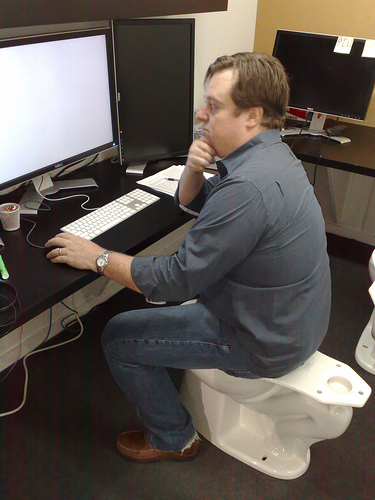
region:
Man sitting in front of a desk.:
[73, 1, 356, 491]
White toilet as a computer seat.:
[155, 318, 365, 493]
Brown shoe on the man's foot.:
[96, 420, 226, 470]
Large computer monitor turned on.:
[0, 8, 131, 178]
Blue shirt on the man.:
[124, 121, 344, 384]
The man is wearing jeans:
[90, 282, 296, 451]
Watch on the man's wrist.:
[94, 243, 118, 285]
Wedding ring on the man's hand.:
[55, 245, 68, 256]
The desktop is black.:
[3, 115, 257, 337]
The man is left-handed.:
[0, 211, 132, 280]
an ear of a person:
[246, 103, 262, 131]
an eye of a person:
[204, 95, 224, 113]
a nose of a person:
[194, 102, 209, 122]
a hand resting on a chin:
[184, 134, 220, 175]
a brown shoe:
[110, 431, 212, 461]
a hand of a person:
[44, 231, 93, 271]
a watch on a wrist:
[92, 246, 113, 275]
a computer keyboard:
[60, 200, 165, 231]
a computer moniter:
[276, 23, 374, 141]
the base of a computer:
[21, 173, 100, 212]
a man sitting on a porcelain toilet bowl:
[41, 43, 369, 484]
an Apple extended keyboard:
[51, 184, 166, 248]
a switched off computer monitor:
[263, 25, 373, 147]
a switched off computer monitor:
[106, 14, 195, 173]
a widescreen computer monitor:
[0, 25, 117, 216]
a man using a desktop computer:
[2, 23, 334, 465]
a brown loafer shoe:
[109, 428, 204, 466]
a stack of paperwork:
[136, 155, 211, 203]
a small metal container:
[0, 201, 24, 233]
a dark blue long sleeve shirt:
[126, 140, 338, 380]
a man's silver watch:
[90, 245, 114, 280]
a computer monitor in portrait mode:
[103, 13, 198, 168]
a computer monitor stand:
[281, 106, 349, 145]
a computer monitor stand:
[12, 168, 98, 211]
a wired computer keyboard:
[31, 176, 161, 240]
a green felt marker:
[0, 252, 10, 279]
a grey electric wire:
[0, 290, 85, 420]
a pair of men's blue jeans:
[98, 293, 283, 447]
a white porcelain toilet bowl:
[351, 231, 374, 375]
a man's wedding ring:
[53, 245, 62, 257]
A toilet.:
[168, 314, 370, 493]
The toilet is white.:
[179, 327, 372, 493]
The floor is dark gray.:
[27, 419, 98, 498]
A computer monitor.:
[259, 21, 373, 132]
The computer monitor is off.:
[259, 22, 374, 129]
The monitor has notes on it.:
[265, 21, 372, 127]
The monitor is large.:
[0, 26, 135, 205]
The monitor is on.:
[0, 17, 137, 207]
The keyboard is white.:
[49, 181, 170, 260]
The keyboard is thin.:
[58, 185, 166, 247]